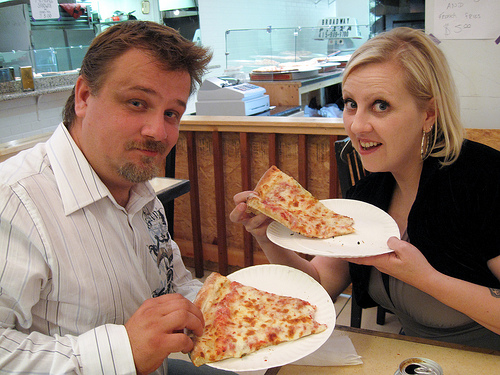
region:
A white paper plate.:
[264, 180, 416, 277]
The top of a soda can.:
[396, 347, 448, 374]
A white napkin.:
[277, 319, 362, 372]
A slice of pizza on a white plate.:
[186, 242, 340, 373]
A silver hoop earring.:
[413, 125, 437, 162]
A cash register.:
[200, 67, 275, 124]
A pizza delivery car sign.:
[309, 13, 366, 45]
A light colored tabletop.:
[248, 312, 498, 369]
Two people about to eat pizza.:
[3, 11, 498, 372]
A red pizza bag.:
[60, 0, 92, 22]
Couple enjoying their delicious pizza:
[55, 12, 476, 370]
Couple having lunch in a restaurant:
[47, 15, 460, 371]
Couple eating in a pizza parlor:
[41, 15, 467, 373]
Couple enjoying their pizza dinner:
[43, 10, 474, 371]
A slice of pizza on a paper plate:
[185, 271, 337, 367]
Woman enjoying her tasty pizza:
[230, 22, 496, 272]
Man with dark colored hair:
[60, 11, 212, 199]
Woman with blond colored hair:
[326, 20, 466, 187]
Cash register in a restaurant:
[190, 67, 277, 119]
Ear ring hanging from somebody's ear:
[408, 117, 438, 163]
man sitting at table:
[0, 20, 211, 370]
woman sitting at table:
[232, 25, 499, 343]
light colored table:
[275, 325, 498, 374]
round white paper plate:
[204, 262, 336, 372]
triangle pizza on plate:
[189, 271, 323, 367]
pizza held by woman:
[245, 165, 355, 240]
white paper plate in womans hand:
[267, 197, 402, 259]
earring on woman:
[418, 126, 435, 152]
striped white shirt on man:
[0, 116, 207, 373]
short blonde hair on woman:
[341, 27, 467, 167]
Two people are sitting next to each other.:
[0, 15, 498, 371]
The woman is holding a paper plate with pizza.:
[220, 6, 488, 298]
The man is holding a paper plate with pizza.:
[0, 20, 367, 371]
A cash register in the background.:
[186, 56, 283, 127]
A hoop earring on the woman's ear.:
[412, 115, 439, 167]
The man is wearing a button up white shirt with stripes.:
[0, 126, 230, 372]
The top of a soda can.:
[386, 341, 451, 372]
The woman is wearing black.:
[305, 140, 496, 316]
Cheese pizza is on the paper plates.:
[175, 128, 387, 371]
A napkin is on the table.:
[305, 327, 371, 369]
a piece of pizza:
[244, 162, 353, 241]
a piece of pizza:
[190, 269, 321, 369]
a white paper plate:
[262, 197, 402, 257]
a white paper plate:
[197, 259, 335, 372]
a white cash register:
[193, 72, 268, 119]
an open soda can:
[395, 356, 437, 373]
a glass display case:
[222, 20, 366, 82]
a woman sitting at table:
[227, 44, 497, 347]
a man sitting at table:
[0, 19, 211, 373]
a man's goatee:
[113, 134, 163, 184]